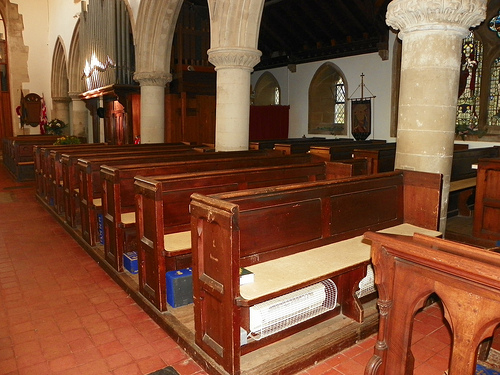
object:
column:
[208, 0, 266, 153]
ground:
[460, 192, 475, 227]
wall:
[283, 72, 305, 137]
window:
[303, 61, 348, 138]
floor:
[0, 162, 500, 374]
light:
[84, 53, 115, 92]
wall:
[0, 0, 53, 95]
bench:
[186, 167, 444, 375]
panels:
[206, 169, 405, 270]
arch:
[253, 70, 281, 105]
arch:
[308, 61, 349, 135]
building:
[0, 0, 500, 375]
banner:
[347, 72, 376, 141]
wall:
[344, 54, 387, 139]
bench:
[99, 153, 319, 274]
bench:
[74, 149, 258, 244]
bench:
[133, 159, 352, 313]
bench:
[341, 138, 393, 173]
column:
[385, 0, 488, 239]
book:
[240, 267, 255, 286]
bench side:
[35, 145, 48, 201]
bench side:
[325, 160, 353, 180]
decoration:
[361, 230, 500, 374]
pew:
[471, 152, 498, 243]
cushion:
[237, 221, 445, 300]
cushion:
[165, 230, 192, 253]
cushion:
[121, 211, 136, 224]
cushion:
[92, 197, 104, 205]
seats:
[161, 229, 192, 267]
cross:
[347, 72, 376, 101]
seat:
[239, 223, 446, 348]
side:
[189, 193, 241, 375]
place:
[16, 67, 423, 302]